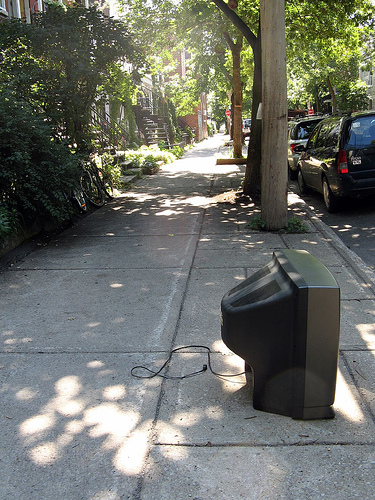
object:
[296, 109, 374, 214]
car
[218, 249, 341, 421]
television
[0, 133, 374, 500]
roadside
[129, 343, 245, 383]
cable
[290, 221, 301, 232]
grass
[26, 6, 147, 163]
tree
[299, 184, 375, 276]
road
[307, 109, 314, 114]
sign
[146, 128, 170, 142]
steps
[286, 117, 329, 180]
car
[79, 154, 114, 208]
bicyle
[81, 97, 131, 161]
rod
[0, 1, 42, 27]
house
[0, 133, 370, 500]
street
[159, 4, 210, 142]
houses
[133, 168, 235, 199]
shade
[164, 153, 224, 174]
reflection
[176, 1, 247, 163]
tree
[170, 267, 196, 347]
crack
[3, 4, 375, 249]
neigborhood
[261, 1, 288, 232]
pole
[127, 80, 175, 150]
staircase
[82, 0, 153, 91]
house